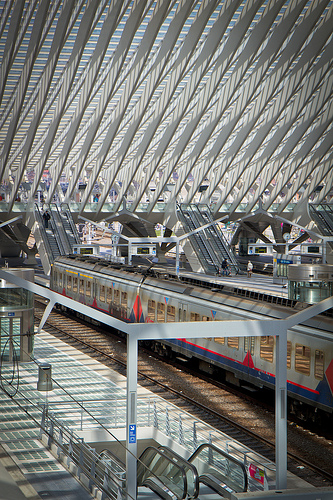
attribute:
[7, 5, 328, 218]
beams — long, steel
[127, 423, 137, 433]
arrow — white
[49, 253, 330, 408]
train — for passengers, white, gray, striped, silver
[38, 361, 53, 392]
can — for trashing, gray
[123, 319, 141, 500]
supporting structure — tall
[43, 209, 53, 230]
person — coming down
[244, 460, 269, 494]
pylons — orange, white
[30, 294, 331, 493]
train tracks — empty, brown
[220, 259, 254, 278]
people — walking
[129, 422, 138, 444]
sign — directional, blue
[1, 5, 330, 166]
sky — blue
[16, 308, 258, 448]
platform — white, empty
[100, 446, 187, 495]
handrail — black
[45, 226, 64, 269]
steps — gray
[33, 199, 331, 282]
escalators — three in count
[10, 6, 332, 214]
ceiling structure — interesting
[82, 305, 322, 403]
stripe — blue, red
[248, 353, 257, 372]
triangle — red